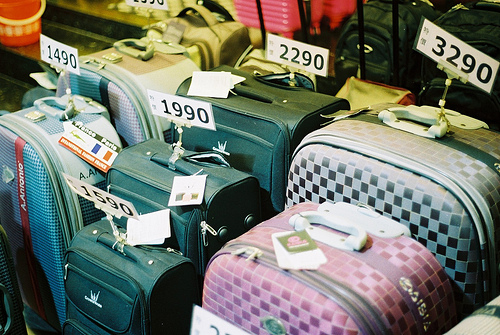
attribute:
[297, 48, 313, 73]
9 — black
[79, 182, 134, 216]
number — black, 1590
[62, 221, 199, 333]
luggage — Small, black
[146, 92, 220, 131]
sign — Rectangle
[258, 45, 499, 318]
bag — black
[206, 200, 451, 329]
luggage — pink, checkered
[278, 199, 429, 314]
luggage — pink, checkered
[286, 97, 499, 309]
suitcase — grey, black, checked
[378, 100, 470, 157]
handle — white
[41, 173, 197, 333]
bag — black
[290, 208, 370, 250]
handle — white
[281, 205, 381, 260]
handles — white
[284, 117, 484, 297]
luggage — black, grey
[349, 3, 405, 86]
handle — black